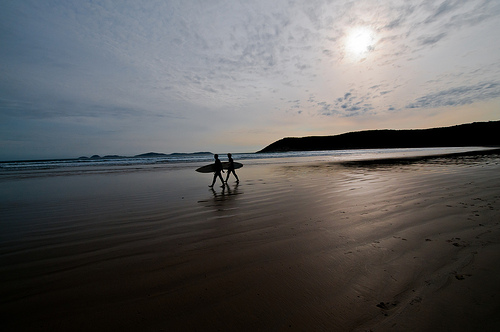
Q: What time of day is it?
A: Nearing sunset.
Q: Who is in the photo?
A: Two surfers.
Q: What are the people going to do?
A: Go surfing.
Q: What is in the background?
A: Long, low mountains.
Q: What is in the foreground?
A: A sandy beach.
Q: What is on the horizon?
A: The ocean on the left, mountains on the right.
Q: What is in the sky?
A: A low sun and some white, wispy clouds.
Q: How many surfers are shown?
A: 2.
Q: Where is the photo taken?
A: On the beach.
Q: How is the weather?
A: Partly cloudy.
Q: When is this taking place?
A: Evening.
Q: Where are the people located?
A: Beach.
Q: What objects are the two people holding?
A: Surfboard.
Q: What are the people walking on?
A: Sand.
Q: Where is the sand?
A: In front of the water.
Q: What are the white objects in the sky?
A: Clouds.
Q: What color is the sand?
A: Tan.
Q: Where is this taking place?
A: At the beach.